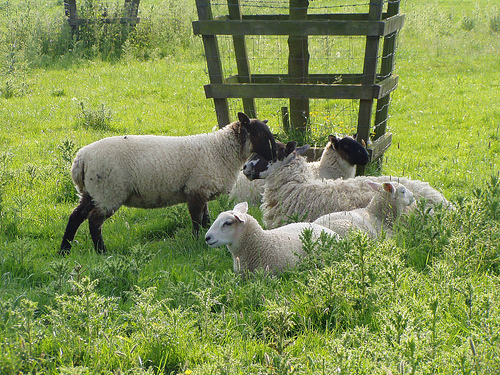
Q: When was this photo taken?
A: During daylight hours.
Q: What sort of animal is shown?
A: Sheep.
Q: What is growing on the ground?
A: Grass.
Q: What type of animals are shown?
A: Sheep.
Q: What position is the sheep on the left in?
A: Standing.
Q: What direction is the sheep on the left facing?
A: Right.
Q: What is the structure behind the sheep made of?
A: Wood.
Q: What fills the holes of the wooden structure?
A: Wire fence.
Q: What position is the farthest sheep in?
A: Laying.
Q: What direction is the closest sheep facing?
A: Left.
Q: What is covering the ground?
A: Grass.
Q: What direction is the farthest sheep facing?
A: Right.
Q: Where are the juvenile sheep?
A: The two closest to the camera.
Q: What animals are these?
A: Sheep.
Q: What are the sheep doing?
A: Resting.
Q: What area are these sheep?
A: Meadow.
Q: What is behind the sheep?
A: Wooden fencing.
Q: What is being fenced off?
A: Trees.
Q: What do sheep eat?
A: Grass.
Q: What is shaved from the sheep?
A: Their hide.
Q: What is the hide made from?
A: Wool.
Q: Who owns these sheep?
A: Farmer.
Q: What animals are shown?
A: Sheep.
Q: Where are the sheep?
A: A grassy field.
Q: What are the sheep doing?
A: Standing and laying in the grass.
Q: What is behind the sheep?
A: A fenced in tree.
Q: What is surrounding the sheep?
A: Grass.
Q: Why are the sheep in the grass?
A: They are grazing.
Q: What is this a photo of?
A: Sheep.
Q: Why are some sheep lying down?
A: To rest.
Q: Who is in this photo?
A: Four sheep.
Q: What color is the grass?
A: Green.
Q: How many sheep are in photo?
A: Four.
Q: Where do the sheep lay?
A: On the grass.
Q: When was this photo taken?
A: In the daytime.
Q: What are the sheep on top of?
A: Grass.